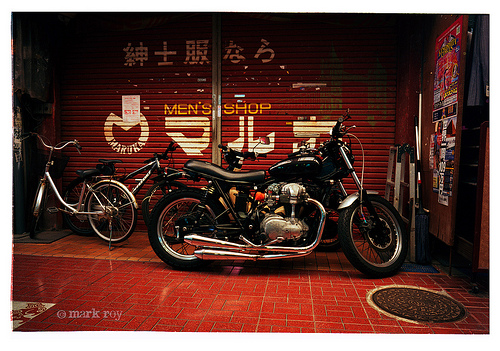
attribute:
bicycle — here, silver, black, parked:
[17, 130, 142, 247]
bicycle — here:
[76, 142, 196, 234]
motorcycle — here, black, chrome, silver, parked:
[145, 102, 412, 277]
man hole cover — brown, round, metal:
[367, 283, 468, 325]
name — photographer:
[58, 301, 132, 320]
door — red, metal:
[64, 19, 400, 204]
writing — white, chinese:
[105, 29, 344, 161]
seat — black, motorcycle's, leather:
[76, 164, 110, 176]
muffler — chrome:
[181, 198, 328, 265]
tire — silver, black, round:
[83, 175, 139, 243]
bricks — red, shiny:
[15, 225, 492, 324]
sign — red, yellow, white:
[88, 30, 322, 169]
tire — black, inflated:
[337, 191, 411, 277]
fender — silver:
[338, 184, 385, 210]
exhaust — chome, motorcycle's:
[179, 190, 330, 264]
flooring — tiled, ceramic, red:
[16, 224, 485, 322]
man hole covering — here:
[365, 279, 469, 325]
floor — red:
[16, 213, 490, 331]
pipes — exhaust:
[184, 199, 327, 261]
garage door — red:
[416, 15, 479, 251]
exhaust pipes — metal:
[181, 196, 330, 261]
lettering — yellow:
[158, 100, 275, 118]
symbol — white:
[100, 91, 344, 160]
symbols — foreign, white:
[114, 28, 278, 74]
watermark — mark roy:
[52, 308, 130, 324]